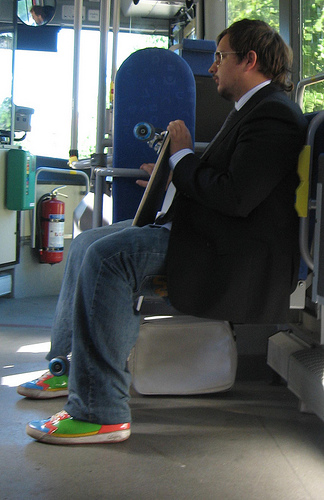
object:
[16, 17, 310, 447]
man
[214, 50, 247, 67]
eyeglasses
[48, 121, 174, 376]
skateboard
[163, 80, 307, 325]
coat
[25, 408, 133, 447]
sneakers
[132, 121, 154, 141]
wheels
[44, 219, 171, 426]
jeans